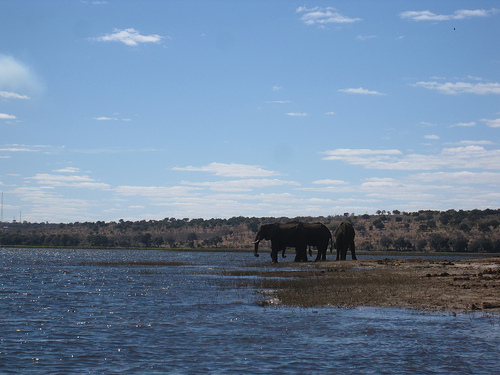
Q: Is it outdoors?
A: Yes, it is outdoors.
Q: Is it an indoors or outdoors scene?
A: It is outdoors.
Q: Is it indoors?
A: No, it is outdoors.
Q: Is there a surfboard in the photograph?
A: No, there are no surfboards.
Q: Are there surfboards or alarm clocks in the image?
A: No, there are no surfboards or alarm clocks.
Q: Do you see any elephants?
A: Yes, there is an elephant.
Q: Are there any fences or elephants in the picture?
A: Yes, there is an elephant.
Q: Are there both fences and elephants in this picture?
A: No, there is an elephant but no fences.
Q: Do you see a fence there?
A: No, there are no fences.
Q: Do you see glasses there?
A: No, there are no glasses.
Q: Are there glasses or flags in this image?
A: No, there are no glasses or flags.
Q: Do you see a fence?
A: No, there are no fences.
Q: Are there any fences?
A: No, there are no fences.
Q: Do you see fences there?
A: No, there are no fences.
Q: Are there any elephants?
A: Yes, there is an elephant.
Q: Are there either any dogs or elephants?
A: Yes, there is an elephant.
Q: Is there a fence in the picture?
A: No, there are no fences.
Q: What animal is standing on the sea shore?
A: The animal is an elephant.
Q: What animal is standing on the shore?
A: The animal is an elephant.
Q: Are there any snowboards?
A: No, there are no snowboards.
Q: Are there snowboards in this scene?
A: No, there are no snowboards.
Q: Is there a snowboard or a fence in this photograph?
A: No, there are no snowboards or fences.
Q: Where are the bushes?
A: The bushes are on the hillside.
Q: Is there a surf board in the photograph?
A: No, there are no surfboards.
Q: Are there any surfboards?
A: No, there are no surfboards.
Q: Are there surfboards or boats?
A: No, there are no surfboards or boats.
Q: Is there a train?
A: No, there are no trains.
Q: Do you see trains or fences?
A: No, there are no trains or fences.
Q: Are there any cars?
A: No, there are no cars.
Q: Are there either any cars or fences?
A: No, there are no cars or fences.